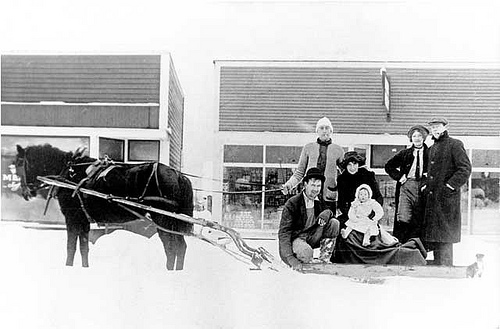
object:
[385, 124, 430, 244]
smiling woman